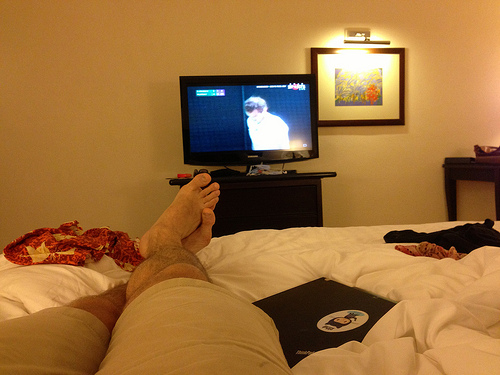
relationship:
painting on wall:
[312, 47, 408, 126] [3, 1, 498, 242]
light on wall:
[343, 25, 391, 46] [3, 1, 498, 242]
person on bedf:
[1, 173, 276, 373] [2, 217, 497, 374]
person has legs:
[1, 173, 276, 373] [3, 173, 274, 373]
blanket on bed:
[0, 221, 498, 372] [3, 221, 496, 374]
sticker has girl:
[316, 308, 369, 332] [328, 311, 363, 329]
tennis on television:
[187, 85, 310, 151] [177, 74, 318, 165]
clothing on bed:
[0, 217, 139, 274] [3, 221, 496, 374]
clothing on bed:
[386, 218, 499, 257] [3, 221, 496, 374]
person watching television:
[1, 173, 276, 373] [177, 74, 318, 165]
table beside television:
[443, 156, 499, 221] [177, 74, 318, 165]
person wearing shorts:
[1, 173, 276, 373] [0, 286, 285, 371]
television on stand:
[177, 74, 318, 165] [173, 171, 337, 231]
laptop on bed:
[249, 271, 402, 367] [3, 221, 496, 374]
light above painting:
[343, 25, 391, 46] [312, 47, 408, 126]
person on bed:
[1, 173, 276, 373] [3, 221, 496, 374]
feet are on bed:
[137, 170, 220, 260] [3, 221, 496, 374]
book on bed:
[249, 271, 402, 367] [3, 221, 496, 374]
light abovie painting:
[343, 25, 391, 46] [312, 47, 408, 126]